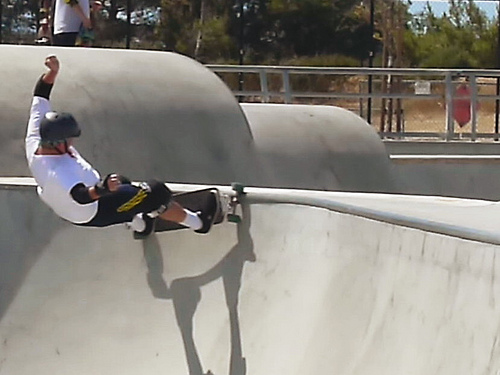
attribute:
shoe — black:
[131, 209, 158, 242]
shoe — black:
[194, 183, 221, 234]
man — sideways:
[23, 86, 243, 236]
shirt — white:
[22, 103, 92, 223]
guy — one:
[9, 50, 234, 232]